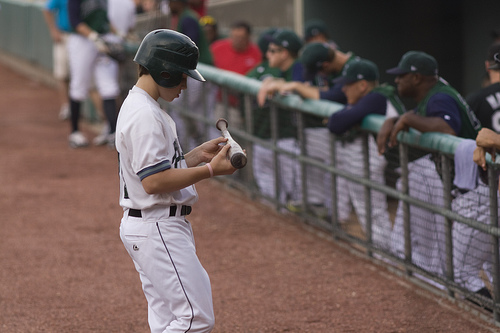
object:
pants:
[113, 207, 215, 332]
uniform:
[114, 87, 214, 333]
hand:
[206, 145, 247, 175]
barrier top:
[96, 34, 500, 162]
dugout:
[150, 0, 499, 318]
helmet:
[131, 28, 205, 90]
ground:
[0, 57, 499, 332]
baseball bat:
[215, 118, 247, 169]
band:
[206, 163, 214, 179]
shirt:
[211, 40, 261, 106]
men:
[377, 52, 479, 153]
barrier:
[121, 42, 496, 331]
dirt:
[0, 58, 499, 333]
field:
[0, 52, 497, 332]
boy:
[110, 29, 243, 333]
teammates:
[327, 56, 407, 138]